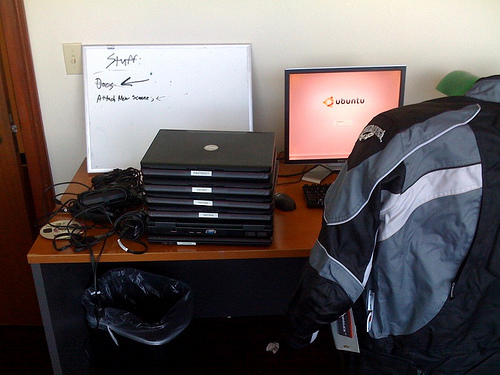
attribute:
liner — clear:
[79, 266, 197, 333]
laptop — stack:
[137, 155, 273, 179]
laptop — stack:
[143, 180, 271, 200]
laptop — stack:
[141, 194, 274, 214]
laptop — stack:
[140, 204, 272, 222]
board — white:
[84, 44, 253, 174]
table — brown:
[27, 156, 340, 375]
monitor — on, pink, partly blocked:
[282, 66, 409, 165]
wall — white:
[270, 3, 499, 65]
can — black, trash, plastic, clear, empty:
[81, 266, 196, 372]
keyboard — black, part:
[304, 182, 330, 210]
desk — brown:
[26, 157, 341, 272]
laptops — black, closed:
[141, 127, 279, 246]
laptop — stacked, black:
[146, 210, 271, 222]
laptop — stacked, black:
[144, 195, 270, 209]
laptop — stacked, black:
[143, 181, 271, 197]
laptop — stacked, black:
[138, 163, 274, 184]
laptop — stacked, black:
[143, 222, 274, 238]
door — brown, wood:
[0, 89, 35, 329]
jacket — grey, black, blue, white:
[278, 74, 498, 374]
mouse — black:
[275, 191, 299, 214]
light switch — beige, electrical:
[62, 42, 83, 76]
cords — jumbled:
[40, 166, 143, 264]